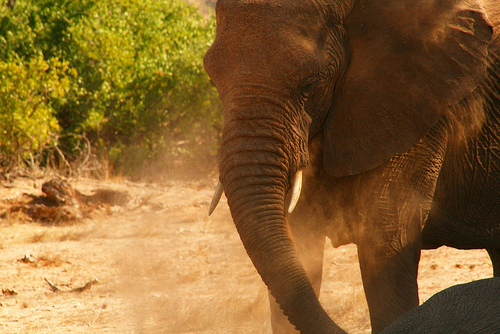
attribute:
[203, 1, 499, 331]
elephant — brown, big, looking, dusty, huge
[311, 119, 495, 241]
skin — wrinkled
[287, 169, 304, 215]
tusk — white, small, yellow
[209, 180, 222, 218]
tusk — white, small, yellow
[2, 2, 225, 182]
bush — green, full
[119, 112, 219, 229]
sand — floating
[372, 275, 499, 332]
elephant — small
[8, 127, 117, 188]
branches — broken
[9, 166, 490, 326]
ground — dry, flat, brown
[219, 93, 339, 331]
trunk — long, curled, wrinkly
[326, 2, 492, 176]
ear — big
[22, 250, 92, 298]
clump — large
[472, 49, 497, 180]
lines — curvy, short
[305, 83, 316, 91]
eye — small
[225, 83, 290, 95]
line — here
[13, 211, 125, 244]
grass — dry